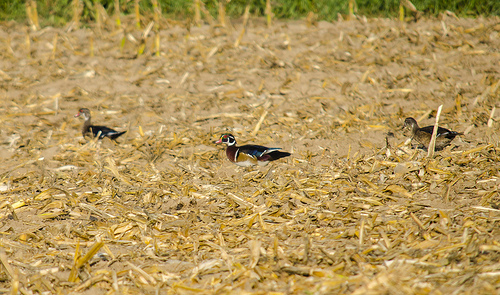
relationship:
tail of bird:
[270, 145, 294, 159] [214, 133, 290, 171]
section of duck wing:
[254, 149, 261, 156] [249, 142, 286, 159]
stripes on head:
[224, 132, 239, 149] [212, 128, 240, 150]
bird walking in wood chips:
[208, 129, 293, 172] [126, 167, 418, 244]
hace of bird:
[400, 115, 417, 132] [394, 113, 464, 153]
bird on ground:
[400, 114, 464, 148] [2, 1, 496, 292]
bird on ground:
[214, 133, 290, 171] [2, 1, 496, 292]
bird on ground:
[74, 105, 128, 142] [2, 1, 496, 292]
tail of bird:
[449, 127, 465, 142] [394, 105, 489, 170]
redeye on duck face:
[223, 135, 227, 141] [399, 115, 414, 127]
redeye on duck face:
[81, 109, 84, 114] [216, 131, 237, 145]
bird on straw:
[214, 133, 290, 171] [124, 163, 257, 252]